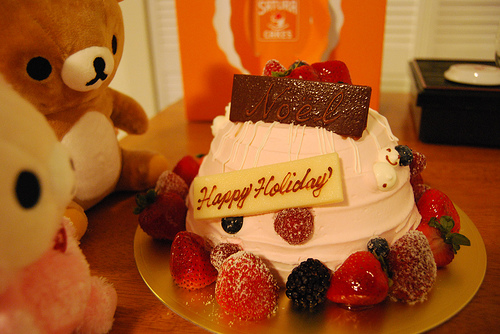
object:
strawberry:
[417, 186, 461, 235]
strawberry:
[414, 213, 472, 267]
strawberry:
[133, 186, 187, 238]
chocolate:
[229, 74, 372, 140]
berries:
[327, 251, 388, 305]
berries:
[391, 228, 438, 302]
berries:
[284, 258, 332, 309]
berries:
[213, 249, 281, 318]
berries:
[417, 187, 463, 232]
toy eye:
[13, 168, 44, 210]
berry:
[213, 247, 283, 324]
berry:
[170, 229, 216, 289]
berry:
[137, 189, 187, 242]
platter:
[133, 198, 487, 332]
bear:
[2, 0, 173, 243]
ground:
[383, 120, 455, 171]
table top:
[78, 90, 499, 332]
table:
[439, 124, 492, 218]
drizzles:
[312, 126, 335, 148]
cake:
[130, 58, 472, 321]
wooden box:
[409, 59, 500, 150]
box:
[147, 0, 413, 123]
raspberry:
[275, 208, 314, 245]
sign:
[193, 151, 347, 219]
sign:
[228, 74, 373, 138]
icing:
[372, 146, 397, 195]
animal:
[3, 76, 118, 329]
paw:
[129, 111, 150, 134]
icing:
[182, 104, 422, 288]